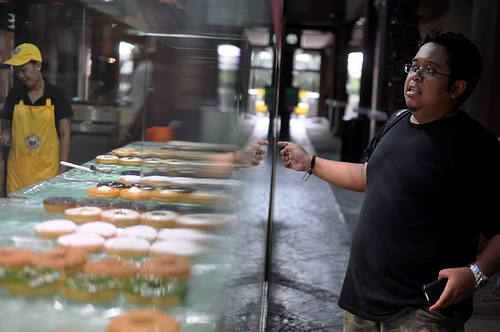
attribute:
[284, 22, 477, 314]
man — light skinned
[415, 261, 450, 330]
phone — black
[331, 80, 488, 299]
tshirt — black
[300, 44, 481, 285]
man — light skinned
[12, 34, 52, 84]
cap — yellow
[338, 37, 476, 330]
man — fat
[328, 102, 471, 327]
belly — fat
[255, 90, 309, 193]
hand — short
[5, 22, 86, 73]
cap — yellow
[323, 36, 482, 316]
man — fat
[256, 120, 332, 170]
hand — short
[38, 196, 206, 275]
cakes — queen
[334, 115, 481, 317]
tshirt — black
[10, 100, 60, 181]
apron — yellow